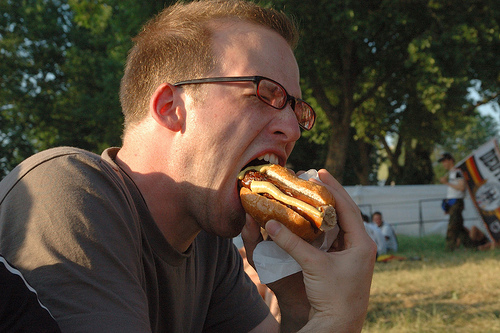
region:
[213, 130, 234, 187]
part of a cheek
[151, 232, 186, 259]
part of a collar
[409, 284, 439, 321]
part of a shade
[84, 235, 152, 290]
part of a shirt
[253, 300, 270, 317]
edge of a sleeve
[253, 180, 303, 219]
part of a bread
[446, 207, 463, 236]
part of a trouser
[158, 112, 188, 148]
edge of an ear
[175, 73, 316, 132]
this is a pair of spectacles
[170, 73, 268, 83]
the frame is black in color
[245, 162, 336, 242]
this is a hotdog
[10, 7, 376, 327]
this is a man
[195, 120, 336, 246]
the man is eating a hotdog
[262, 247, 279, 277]
this is a serviette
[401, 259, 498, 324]
this is the grass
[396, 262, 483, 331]
the grass is green in color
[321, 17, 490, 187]
this is a tree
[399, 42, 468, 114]
the leaves are green in color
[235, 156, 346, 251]
a half eaten hot dog.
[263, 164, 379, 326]
a hand holding food.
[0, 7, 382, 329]
a human male eating.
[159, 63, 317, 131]
hipster style sunglasses.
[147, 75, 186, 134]
right male human ear.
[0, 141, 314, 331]
a brown t shirt.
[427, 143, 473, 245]
a man standing in a field.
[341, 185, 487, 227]
a white wall in a field.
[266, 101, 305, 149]
human male nose.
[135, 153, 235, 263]
human neck.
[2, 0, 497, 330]
a man outdoors eating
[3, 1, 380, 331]
a man eating a hot dog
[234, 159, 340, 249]
a partially eaten hot dog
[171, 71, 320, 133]
a man's pair of eyeglasses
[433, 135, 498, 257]
a man holding a flag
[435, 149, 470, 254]
a man wearing a ball cap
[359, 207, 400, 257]
people sitting on grass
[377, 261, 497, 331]
a patch of grass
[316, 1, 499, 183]
a few shade trees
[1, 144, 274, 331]
a man's brown t-shirt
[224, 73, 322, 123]
The eyeglasses the man is wearing.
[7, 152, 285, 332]
The t-shirt the man is wearing.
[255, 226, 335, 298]
The white napkin in the guy's hand.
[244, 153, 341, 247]
The sandwich the man is biting into.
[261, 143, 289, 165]
The teeth of the man biting into the sandwich.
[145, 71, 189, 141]
The ear of the man biting into the sandwich.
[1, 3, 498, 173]
The trees in the background.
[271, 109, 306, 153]
The nose and nostrils of the man biting into the sandwich.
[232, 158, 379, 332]
The man's hands holding the sadwich.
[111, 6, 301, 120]
The hair of the man biting into the sandwich.